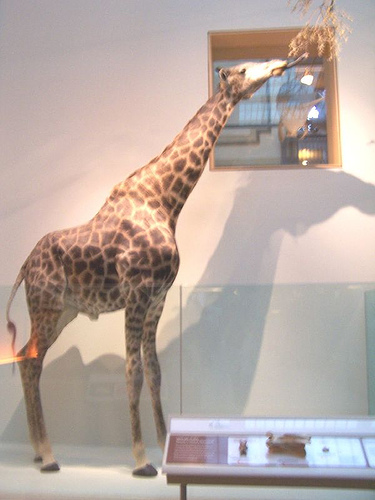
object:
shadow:
[1, 166, 373, 467]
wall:
[1, 1, 370, 484]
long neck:
[116, 97, 240, 234]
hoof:
[41, 460, 60, 469]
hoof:
[133, 462, 157, 477]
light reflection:
[297, 70, 321, 87]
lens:
[0, 345, 23, 363]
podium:
[232, 426, 328, 476]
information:
[167, 422, 367, 469]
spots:
[103, 194, 173, 262]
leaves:
[292, 1, 348, 52]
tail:
[6, 265, 26, 377]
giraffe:
[4, 57, 290, 478]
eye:
[238, 66, 248, 76]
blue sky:
[219, 415, 371, 485]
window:
[205, 32, 342, 173]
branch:
[286, 0, 350, 60]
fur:
[48, 234, 148, 274]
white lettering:
[177, 437, 216, 459]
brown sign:
[167, 433, 214, 463]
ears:
[214, 65, 228, 82]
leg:
[141, 298, 179, 463]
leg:
[16, 309, 56, 456]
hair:
[5, 324, 18, 379]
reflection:
[276, 84, 310, 148]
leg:
[126, 285, 157, 461]